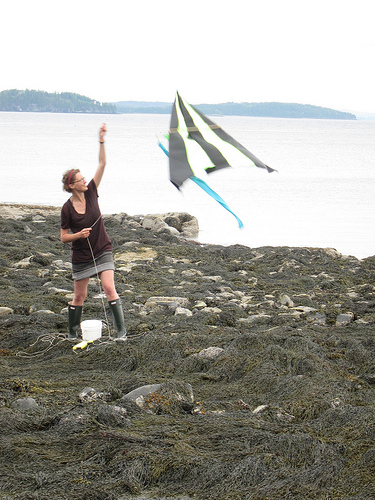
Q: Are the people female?
A: Yes, all the people are female.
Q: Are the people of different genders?
A: No, all the people are female.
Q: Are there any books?
A: No, there are no books.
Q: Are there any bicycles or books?
A: No, there are no books or bicycles.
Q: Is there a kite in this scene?
A: Yes, there is a kite.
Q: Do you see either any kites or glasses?
A: Yes, there is a kite.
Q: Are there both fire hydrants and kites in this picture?
A: No, there is a kite but no fire hydrants.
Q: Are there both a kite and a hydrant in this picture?
A: No, there is a kite but no fire hydrants.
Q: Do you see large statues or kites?
A: Yes, there is a large kite.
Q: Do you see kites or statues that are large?
A: Yes, the kite is large.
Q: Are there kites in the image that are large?
A: Yes, there is a large kite.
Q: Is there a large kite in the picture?
A: Yes, there is a large kite.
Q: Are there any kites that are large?
A: Yes, there is a large kite.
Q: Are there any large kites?
A: Yes, there is a large kite.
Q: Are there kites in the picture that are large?
A: Yes, there is a kite that is large.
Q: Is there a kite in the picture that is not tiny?
A: Yes, there is a large kite.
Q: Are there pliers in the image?
A: No, there are no pliers.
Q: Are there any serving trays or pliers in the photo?
A: No, there are no pliers or serving trays.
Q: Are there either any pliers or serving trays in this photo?
A: No, there are no pliers or serving trays.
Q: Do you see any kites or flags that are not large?
A: No, there is a kite but it is large.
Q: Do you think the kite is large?
A: Yes, the kite is large.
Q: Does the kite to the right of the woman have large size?
A: Yes, the kite is large.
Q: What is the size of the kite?
A: The kite is large.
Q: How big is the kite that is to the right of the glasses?
A: The kite is large.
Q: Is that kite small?
A: No, the kite is large.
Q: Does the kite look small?
A: No, the kite is large.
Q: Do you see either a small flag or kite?
A: No, there is a kite but it is large.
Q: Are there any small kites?
A: No, there is a kite but it is large.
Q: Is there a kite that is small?
A: No, there is a kite but it is large.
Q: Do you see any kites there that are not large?
A: No, there is a kite but it is large.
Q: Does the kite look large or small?
A: The kite is large.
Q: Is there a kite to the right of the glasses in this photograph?
A: Yes, there is a kite to the right of the glasses.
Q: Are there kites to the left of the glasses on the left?
A: No, the kite is to the right of the glasses.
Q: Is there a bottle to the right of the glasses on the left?
A: No, there is a kite to the right of the glasses.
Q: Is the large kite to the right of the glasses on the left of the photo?
A: Yes, the kite is to the right of the glasses.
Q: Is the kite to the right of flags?
A: No, the kite is to the right of the glasses.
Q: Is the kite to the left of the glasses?
A: No, the kite is to the right of the glasses.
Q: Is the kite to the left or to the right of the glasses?
A: The kite is to the right of the glasses.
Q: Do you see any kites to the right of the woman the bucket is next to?
A: Yes, there is a kite to the right of the woman.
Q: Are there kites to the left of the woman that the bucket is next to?
A: No, the kite is to the right of the woman.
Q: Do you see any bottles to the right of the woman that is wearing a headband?
A: No, there is a kite to the right of the woman.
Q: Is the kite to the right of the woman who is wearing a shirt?
A: Yes, the kite is to the right of the woman.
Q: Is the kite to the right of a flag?
A: No, the kite is to the right of the woman.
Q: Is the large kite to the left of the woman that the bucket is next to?
A: No, the kite is to the right of the woman.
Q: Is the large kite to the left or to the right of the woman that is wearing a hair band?
A: The kite is to the right of the woman.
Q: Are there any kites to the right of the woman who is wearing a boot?
A: Yes, there is a kite to the right of the woman.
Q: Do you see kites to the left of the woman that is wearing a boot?
A: No, the kite is to the right of the woman.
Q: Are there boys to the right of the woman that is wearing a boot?
A: No, there is a kite to the right of the woman.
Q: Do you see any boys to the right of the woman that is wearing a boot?
A: No, there is a kite to the right of the woman.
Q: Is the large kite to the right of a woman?
A: Yes, the kite is to the right of a woman.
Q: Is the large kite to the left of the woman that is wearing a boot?
A: No, the kite is to the right of the woman.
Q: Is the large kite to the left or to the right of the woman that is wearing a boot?
A: The kite is to the right of the woman.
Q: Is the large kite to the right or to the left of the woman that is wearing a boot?
A: The kite is to the right of the woman.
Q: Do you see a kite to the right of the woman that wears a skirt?
A: Yes, there is a kite to the right of the woman.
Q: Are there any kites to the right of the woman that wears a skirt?
A: Yes, there is a kite to the right of the woman.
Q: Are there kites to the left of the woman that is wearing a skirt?
A: No, the kite is to the right of the woman.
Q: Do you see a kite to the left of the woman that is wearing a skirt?
A: No, the kite is to the right of the woman.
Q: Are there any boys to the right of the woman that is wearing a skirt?
A: No, there is a kite to the right of the woman.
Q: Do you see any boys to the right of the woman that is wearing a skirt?
A: No, there is a kite to the right of the woman.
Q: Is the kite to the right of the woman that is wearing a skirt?
A: Yes, the kite is to the right of the woman.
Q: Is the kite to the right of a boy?
A: No, the kite is to the right of the woman.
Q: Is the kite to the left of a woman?
A: No, the kite is to the right of a woman.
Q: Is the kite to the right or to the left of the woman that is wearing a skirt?
A: The kite is to the right of the woman.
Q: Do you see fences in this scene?
A: No, there are no fences.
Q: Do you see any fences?
A: No, there are no fences.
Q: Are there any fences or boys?
A: No, there are no fences or boys.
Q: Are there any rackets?
A: No, there are no rackets.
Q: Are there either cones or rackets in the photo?
A: No, there are no rackets or cones.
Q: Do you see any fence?
A: No, there are no fences.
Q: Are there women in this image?
A: Yes, there is a woman.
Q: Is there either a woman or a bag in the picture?
A: Yes, there is a woman.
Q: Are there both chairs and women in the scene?
A: No, there is a woman but no chairs.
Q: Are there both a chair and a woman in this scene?
A: No, there is a woman but no chairs.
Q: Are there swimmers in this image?
A: No, there are no swimmers.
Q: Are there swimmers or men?
A: No, there are no swimmers or men.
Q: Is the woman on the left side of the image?
A: Yes, the woman is on the left of the image.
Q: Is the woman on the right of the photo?
A: No, the woman is on the left of the image.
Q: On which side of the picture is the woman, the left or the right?
A: The woman is on the left of the image.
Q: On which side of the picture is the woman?
A: The woman is on the left of the image.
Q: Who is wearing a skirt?
A: The woman is wearing a skirt.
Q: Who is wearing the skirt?
A: The woman is wearing a skirt.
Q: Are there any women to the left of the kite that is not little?
A: Yes, there is a woman to the left of the kite.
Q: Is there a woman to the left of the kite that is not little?
A: Yes, there is a woman to the left of the kite.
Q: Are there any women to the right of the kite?
A: No, the woman is to the left of the kite.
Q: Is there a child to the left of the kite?
A: No, there is a woman to the left of the kite.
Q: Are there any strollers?
A: No, there are no strollers.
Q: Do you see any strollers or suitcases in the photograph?
A: No, there are no strollers or suitcases.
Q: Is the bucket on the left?
A: Yes, the bucket is on the left of the image.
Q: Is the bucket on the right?
A: No, the bucket is on the left of the image.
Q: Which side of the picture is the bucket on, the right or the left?
A: The bucket is on the left of the image.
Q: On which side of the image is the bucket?
A: The bucket is on the left of the image.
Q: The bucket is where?
A: The bucket is on the ground.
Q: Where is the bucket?
A: The bucket is on the ground.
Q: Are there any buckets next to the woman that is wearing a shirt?
A: Yes, there is a bucket next to the woman.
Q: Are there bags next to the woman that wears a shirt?
A: No, there is a bucket next to the woman.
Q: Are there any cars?
A: No, there are no cars.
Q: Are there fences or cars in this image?
A: No, there are no cars or fences.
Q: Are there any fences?
A: No, there are no fences.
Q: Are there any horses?
A: No, there are no horses.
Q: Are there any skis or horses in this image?
A: No, there are no horses or skis.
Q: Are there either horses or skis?
A: No, there are no horses or skis.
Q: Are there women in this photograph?
A: Yes, there is a woman.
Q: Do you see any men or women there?
A: Yes, there is a woman.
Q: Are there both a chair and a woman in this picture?
A: No, there is a woman but no chairs.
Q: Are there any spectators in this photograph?
A: No, there are no spectators.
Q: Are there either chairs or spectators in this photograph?
A: No, there are no spectators or chairs.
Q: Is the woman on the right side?
A: No, the woman is on the left of the image.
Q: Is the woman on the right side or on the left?
A: The woman is on the left of the image.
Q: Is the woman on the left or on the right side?
A: The woman is on the left of the image.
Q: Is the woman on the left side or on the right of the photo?
A: The woman is on the left of the image.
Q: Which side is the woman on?
A: The woman is on the left of the image.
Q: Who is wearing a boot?
A: The woman is wearing a boot.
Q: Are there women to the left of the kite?
A: Yes, there is a woman to the left of the kite.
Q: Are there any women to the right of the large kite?
A: No, the woman is to the left of the kite.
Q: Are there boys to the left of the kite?
A: No, there is a woman to the left of the kite.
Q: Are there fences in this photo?
A: No, there are no fences.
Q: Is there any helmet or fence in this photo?
A: No, there are no fences or helmets.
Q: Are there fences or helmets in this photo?
A: No, there are no fences or helmets.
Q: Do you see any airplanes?
A: No, there are no airplanes.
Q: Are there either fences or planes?
A: No, there are no planes or fences.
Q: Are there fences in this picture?
A: No, there are no fences.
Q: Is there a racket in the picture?
A: No, there are no rackets.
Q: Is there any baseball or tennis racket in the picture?
A: No, there are no rackets or baseballs.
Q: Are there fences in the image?
A: No, there are no fences.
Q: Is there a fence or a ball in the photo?
A: No, there are no fences or balls.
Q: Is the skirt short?
A: Yes, the skirt is short.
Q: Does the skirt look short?
A: Yes, the skirt is short.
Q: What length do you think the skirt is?
A: The skirt is short.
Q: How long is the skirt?
A: The skirt is short.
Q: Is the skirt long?
A: No, the skirt is short.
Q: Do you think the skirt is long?
A: No, the skirt is short.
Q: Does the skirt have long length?
A: No, the skirt is short.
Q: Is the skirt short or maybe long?
A: The skirt is short.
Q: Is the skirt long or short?
A: The skirt is short.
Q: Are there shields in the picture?
A: No, there are no shields.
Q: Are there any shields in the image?
A: No, there are no shields.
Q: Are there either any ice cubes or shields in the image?
A: No, there are no shields or ice cubes.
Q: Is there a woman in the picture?
A: Yes, there is a woman.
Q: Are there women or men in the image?
A: Yes, there is a woman.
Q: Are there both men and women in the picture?
A: No, there is a woman but no men.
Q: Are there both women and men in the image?
A: No, there is a woman but no men.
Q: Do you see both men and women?
A: No, there is a woman but no men.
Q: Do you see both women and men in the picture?
A: No, there is a woman but no men.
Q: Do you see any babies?
A: No, there are no babies.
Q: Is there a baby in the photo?
A: No, there are no babies.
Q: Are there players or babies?
A: No, there are no babies or players.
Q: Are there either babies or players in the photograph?
A: No, there are no babies or players.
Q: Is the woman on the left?
A: Yes, the woman is on the left of the image.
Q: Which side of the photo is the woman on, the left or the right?
A: The woman is on the left of the image.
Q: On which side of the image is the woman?
A: The woman is on the left of the image.